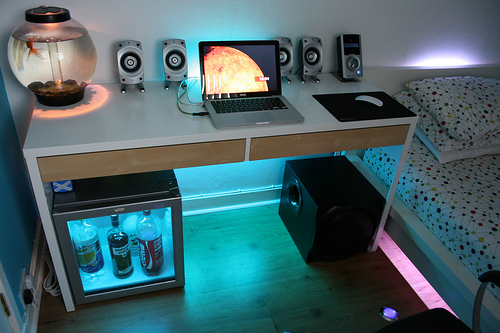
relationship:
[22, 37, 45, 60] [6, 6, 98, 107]
fish in tank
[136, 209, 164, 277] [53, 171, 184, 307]
soda in refrigerator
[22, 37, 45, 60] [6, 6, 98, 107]
goldfish in bowl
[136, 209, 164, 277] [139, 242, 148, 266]
bottle of cola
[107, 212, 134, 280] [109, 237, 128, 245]
bottle of drink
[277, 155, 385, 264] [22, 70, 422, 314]
sub woofer under desk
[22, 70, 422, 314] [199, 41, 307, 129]
desk has computer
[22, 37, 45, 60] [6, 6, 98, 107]
goldfish in aquarium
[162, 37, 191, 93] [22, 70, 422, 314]
speaker on desk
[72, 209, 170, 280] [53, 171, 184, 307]
beverages in fridge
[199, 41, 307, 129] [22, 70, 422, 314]
laptop on desk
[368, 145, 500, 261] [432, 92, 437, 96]
sheet has color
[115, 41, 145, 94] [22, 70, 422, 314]
speaker on top of desk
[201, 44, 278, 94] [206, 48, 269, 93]
screen has sun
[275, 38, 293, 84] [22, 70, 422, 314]
speaker on desk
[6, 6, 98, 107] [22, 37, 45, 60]
bowl has goldfish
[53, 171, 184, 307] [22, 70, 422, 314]
refrigerator under desk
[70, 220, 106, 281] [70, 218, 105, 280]
bottle of beverages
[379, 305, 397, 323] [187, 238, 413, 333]
cell phone on floor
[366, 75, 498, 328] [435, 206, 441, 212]
bed has dot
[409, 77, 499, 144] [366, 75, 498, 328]
pillow on bed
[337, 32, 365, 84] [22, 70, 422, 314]
clock on top of desk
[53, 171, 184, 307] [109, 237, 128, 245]
fridge has drink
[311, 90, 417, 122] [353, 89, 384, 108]
mousepad has mouse